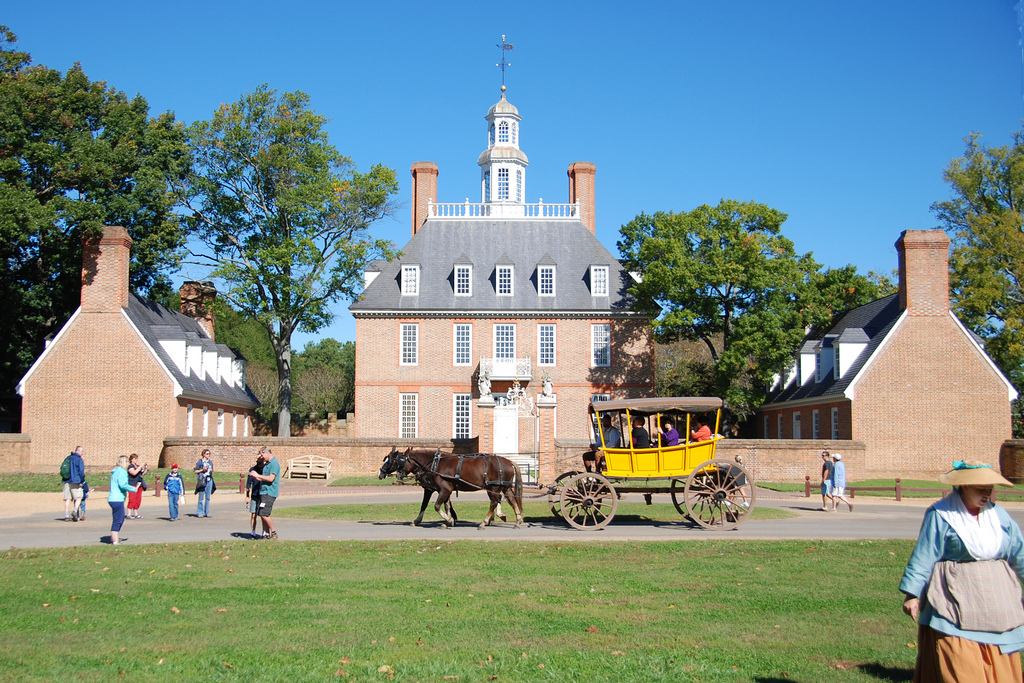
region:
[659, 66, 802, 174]
a view of sky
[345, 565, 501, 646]
a view of grass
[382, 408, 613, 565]
a view of horse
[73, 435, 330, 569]
a view of people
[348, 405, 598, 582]
horse on the road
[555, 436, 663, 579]
wheel of the vehicle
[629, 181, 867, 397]
a view of trees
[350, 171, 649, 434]
a view of building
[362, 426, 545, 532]
horses pulling a wagon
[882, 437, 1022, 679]
woman dressed in old fashioned dress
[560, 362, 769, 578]
yellow wagon being pulled by horses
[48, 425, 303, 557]
people on a street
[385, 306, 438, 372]
window on a building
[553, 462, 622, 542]
wheel of a wagon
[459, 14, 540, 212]
tower on top of a building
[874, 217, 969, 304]
chimney on a building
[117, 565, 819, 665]
green grass of a lawn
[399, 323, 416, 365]
window in front of large brick building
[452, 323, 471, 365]
window in front of large brick building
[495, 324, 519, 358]
window in front of large brick building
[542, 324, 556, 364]
window in front of large brick building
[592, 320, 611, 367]
window in front of large brick building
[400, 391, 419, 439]
window in front of large brick building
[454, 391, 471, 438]
window in front of large brick building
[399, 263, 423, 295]
window in front of large brick building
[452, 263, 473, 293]
window in front of large brick building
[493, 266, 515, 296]
window in front of large brick building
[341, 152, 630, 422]
tan colored house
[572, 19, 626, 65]
white clouds in blue sky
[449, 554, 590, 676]
a view of grass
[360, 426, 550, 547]
a horse in the road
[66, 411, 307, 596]
a group of people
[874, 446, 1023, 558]
a woman in grass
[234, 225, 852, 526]
a view of building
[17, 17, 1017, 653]
a scene of a village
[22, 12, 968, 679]
a scene outside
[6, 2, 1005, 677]
a scene during the daytime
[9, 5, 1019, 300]
a blue sky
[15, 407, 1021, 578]
people on the sidewalk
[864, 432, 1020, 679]
a woman in a dress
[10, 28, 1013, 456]
some green trees in the background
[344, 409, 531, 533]
a couple of brown horses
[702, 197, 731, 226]
green leaves on the tree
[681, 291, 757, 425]
green leaves on the tree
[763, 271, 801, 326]
green leaves on the tree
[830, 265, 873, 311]
green leaves on the tree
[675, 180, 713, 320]
green leaves on the tree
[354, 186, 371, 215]
green leaves on the tree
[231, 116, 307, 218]
green leaves on the tree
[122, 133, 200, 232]
green leaves on the tree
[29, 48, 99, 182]
green leaves on the tree